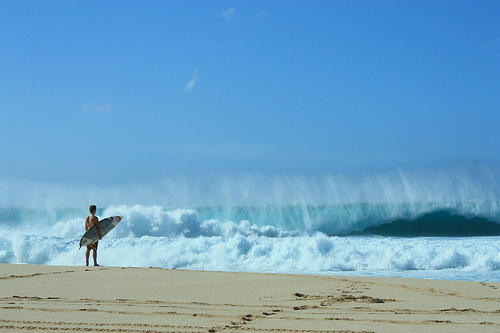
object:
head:
[89, 204, 97, 213]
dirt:
[223, 273, 289, 281]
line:
[233, 272, 331, 280]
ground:
[0, 263, 500, 333]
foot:
[94, 264, 99, 266]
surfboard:
[79, 215, 123, 249]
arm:
[94, 217, 102, 236]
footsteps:
[0, 294, 500, 333]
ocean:
[0, 201, 500, 280]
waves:
[22, 192, 497, 283]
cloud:
[186, 68, 200, 93]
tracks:
[0, 296, 500, 332]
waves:
[0, 167, 500, 280]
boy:
[85, 205, 102, 266]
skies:
[0, 0, 500, 127]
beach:
[0, 265, 499, 333]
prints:
[292, 291, 333, 312]